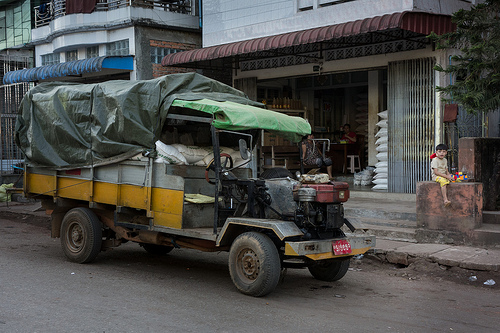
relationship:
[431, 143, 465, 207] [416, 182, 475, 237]
boy sitting in wall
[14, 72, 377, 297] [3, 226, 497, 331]
lorry on road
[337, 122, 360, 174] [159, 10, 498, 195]
woman sitting inside shop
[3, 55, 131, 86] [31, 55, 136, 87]
covering outside shop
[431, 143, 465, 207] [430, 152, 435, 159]
boy had hairband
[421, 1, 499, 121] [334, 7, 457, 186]
tree growing outside shop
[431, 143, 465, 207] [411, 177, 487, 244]
boy sits on wall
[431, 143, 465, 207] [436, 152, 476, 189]
boy holds toy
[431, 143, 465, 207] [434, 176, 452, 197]
boy wears pants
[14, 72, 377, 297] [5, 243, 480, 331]
lorry on street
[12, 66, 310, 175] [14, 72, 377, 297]
canopy drapes on lorry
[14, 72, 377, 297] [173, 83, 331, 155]
lorry covered by canopy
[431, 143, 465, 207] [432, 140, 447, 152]
boy has hair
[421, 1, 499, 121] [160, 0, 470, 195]
tree in front of building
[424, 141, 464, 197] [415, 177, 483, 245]
boy sitting on wall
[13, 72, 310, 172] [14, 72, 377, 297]
canopy over back part of lorry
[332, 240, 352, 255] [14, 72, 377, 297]
number plate in front of lorry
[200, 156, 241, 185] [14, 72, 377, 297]
steering of lorry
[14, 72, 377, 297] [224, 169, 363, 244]
lorry missing hood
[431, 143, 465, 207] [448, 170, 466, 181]
boy playing with toy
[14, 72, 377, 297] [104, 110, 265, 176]
lorry carrying goods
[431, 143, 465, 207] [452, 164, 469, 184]
boy playing with toys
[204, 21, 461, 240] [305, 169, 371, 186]
shop with bags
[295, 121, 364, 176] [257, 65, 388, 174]
women sitting inside shop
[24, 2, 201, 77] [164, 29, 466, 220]
buildings near shop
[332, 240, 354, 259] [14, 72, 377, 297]
number plate on lorry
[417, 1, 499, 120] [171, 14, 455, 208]
tree near shop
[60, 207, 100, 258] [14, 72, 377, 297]
wheel of lorry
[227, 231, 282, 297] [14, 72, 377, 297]
tire of lorry